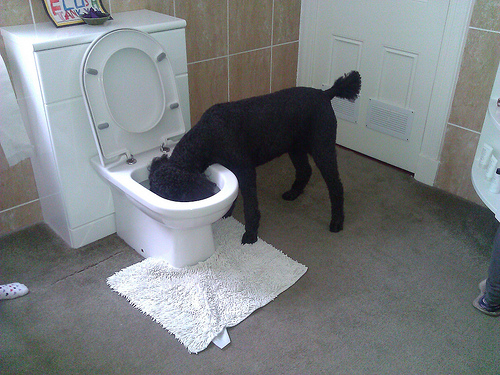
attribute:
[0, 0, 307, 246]
wall — brown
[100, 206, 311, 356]
rug — white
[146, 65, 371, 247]
poodle — black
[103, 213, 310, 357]
floor mat — white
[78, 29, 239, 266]
toilet — upright, white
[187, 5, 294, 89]
tiles — beige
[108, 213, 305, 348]
rug — white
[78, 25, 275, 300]
toilet — white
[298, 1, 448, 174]
door — white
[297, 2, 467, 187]
door — white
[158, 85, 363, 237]
dog — black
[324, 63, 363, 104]
tail — short, black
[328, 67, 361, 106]
tail — short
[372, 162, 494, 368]
floor — grey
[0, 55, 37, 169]
toilet paper — white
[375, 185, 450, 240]
flooring — gray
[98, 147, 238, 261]
bowl — white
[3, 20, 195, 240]
tank — white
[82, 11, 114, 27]
bowl — glass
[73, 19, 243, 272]
toilet — white